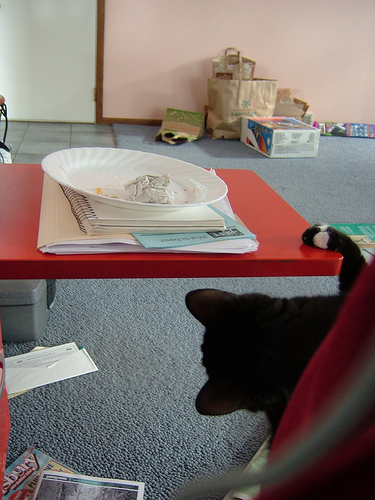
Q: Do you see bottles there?
A: No, there are no bottles.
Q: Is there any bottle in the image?
A: No, there are no bottles.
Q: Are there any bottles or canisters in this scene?
A: No, there are no bottles or canisters.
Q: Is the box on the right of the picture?
A: Yes, the box is on the right of the image.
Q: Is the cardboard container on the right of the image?
A: Yes, the box is on the right of the image.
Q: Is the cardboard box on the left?
A: No, the box is on the right of the image.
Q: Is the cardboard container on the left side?
A: No, the box is on the right of the image.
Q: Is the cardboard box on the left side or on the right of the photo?
A: The box is on the right of the image.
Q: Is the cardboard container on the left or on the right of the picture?
A: The box is on the right of the image.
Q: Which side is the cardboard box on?
A: The box is on the right of the image.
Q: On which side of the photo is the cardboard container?
A: The box is on the right of the image.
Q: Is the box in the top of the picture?
A: Yes, the box is in the top of the image.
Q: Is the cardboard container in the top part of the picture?
A: Yes, the box is in the top of the image.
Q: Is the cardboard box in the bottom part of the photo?
A: No, the box is in the top of the image.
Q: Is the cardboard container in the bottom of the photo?
A: No, the box is in the top of the image.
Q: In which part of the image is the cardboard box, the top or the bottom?
A: The box is in the top of the image.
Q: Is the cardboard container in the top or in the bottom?
A: The box is in the top of the image.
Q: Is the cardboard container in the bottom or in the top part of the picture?
A: The box is in the top of the image.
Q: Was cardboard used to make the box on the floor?
A: Yes, the box is made of cardboard.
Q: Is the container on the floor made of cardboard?
A: Yes, the box is made of cardboard.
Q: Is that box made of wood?
A: No, the box is made of cardboard.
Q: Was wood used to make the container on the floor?
A: No, the box is made of cardboard.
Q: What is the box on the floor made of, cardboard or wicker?
A: The box is made of cardboard.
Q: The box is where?
A: The box is on the floor.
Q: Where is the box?
A: The box is on the floor.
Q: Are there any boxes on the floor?
A: Yes, there is a box on the floor.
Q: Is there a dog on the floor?
A: No, there is a box on the floor.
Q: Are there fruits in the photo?
A: No, there are no fruits.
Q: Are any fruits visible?
A: No, there are no fruits.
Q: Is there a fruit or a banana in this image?
A: No, there are no fruits or bananas.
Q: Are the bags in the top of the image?
A: Yes, the bags are in the top of the image.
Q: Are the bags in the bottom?
A: No, the bags are in the top of the image.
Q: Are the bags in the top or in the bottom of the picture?
A: The bags are in the top of the image.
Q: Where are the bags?
A: The bags are on the floor.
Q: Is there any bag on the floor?
A: Yes, there are bags on the floor.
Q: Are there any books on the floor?
A: No, there are bags on the floor.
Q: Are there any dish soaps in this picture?
A: No, there are no dish soaps.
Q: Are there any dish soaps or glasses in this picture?
A: No, there are no dish soaps or glasses.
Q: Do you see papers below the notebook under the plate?
A: Yes, there are papers below the notebook.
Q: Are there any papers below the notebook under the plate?
A: Yes, there are papers below the notebook.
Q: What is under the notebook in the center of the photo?
A: The papers are under the notebook.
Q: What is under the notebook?
A: The papers are under the notebook.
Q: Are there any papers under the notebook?
A: Yes, there are papers under the notebook.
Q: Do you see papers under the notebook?
A: Yes, there are papers under the notebook.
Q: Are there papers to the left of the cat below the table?
A: Yes, there are papers to the left of the cat.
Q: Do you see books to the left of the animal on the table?
A: No, there are papers to the left of the cat.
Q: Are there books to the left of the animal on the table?
A: No, there are papers to the left of the cat.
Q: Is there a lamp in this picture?
A: No, there are no lamps.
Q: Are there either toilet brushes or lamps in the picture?
A: No, there are no lamps or toilet brushes.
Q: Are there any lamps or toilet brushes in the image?
A: No, there are no lamps or toilet brushes.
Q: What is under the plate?
A: The notebook is under the plate.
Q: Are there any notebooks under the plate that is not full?
A: Yes, there is a notebook under the plate.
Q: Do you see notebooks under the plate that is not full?
A: Yes, there is a notebook under the plate.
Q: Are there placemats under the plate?
A: No, there is a notebook under the plate.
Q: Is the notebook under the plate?
A: Yes, the notebook is under the plate.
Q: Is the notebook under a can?
A: No, the notebook is under the plate.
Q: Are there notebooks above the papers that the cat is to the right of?
A: Yes, there is a notebook above the papers.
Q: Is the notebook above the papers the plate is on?
A: Yes, the notebook is above the papers.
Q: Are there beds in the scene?
A: No, there are no beds.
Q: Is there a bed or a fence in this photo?
A: No, there are no beds or fences.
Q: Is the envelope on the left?
A: Yes, the envelope is on the left of the image.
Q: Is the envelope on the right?
A: No, the envelope is on the left of the image.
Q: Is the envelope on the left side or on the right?
A: The envelope is on the left of the image.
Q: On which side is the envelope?
A: The envelope is on the left of the image.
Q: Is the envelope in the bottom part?
A: Yes, the envelope is in the bottom of the image.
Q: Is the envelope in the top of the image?
A: No, the envelope is in the bottom of the image.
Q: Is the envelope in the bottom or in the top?
A: The envelope is in the bottom of the image.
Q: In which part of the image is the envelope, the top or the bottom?
A: The envelope is in the bottom of the image.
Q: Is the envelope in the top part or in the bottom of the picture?
A: The envelope is in the bottom of the image.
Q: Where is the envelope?
A: The envelope is on the floor.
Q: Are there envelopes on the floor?
A: Yes, there is an envelope on the floor.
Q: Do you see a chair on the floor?
A: No, there is an envelope on the floor.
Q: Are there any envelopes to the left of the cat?
A: Yes, there is an envelope to the left of the cat.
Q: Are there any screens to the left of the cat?
A: No, there is an envelope to the left of the cat.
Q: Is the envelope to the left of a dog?
A: No, the envelope is to the left of the cat.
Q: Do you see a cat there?
A: Yes, there is a cat.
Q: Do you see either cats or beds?
A: Yes, there is a cat.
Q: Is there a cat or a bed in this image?
A: Yes, there is a cat.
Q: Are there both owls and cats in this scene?
A: No, there is a cat but no owls.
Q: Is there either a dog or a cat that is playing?
A: Yes, the cat is playing.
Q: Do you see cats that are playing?
A: Yes, there is a cat that is playing.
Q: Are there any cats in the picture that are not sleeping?
A: Yes, there is a cat that is playing.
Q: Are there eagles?
A: No, there are no eagles.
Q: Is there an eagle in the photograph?
A: No, there are no eagles.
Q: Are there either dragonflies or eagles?
A: No, there are no eagles or dragonflies.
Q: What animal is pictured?
A: The animal is a cat.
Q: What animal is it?
A: The animal is a cat.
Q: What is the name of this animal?
A: This is a cat.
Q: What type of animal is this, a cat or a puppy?
A: This is a cat.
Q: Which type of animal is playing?
A: The animal is a cat.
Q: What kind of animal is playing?
A: The animal is a cat.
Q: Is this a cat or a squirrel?
A: This is a cat.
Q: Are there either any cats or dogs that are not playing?
A: No, there is a cat but it is playing.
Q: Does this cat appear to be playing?
A: Yes, the cat is playing.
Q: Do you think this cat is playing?
A: Yes, the cat is playing.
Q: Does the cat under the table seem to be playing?
A: Yes, the cat is playing.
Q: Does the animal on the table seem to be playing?
A: Yes, the cat is playing.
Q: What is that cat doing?
A: The cat is playing.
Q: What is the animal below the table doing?
A: The cat is playing.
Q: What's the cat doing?
A: The cat is playing.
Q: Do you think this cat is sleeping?
A: No, the cat is playing.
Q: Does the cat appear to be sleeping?
A: No, the cat is playing.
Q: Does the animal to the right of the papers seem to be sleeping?
A: No, the cat is playing.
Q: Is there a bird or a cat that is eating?
A: No, there is a cat but it is playing.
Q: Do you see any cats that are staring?
A: No, there is a cat but it is playing.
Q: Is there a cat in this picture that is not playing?
A: No, there is a cat but it is playing.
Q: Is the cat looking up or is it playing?
A: The cat is playing.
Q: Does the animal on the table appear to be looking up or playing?
A: The cat is playing.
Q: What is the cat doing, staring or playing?
A: The cat is playing.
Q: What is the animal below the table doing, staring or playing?
A: The cat is playing.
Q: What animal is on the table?
A: The animal is a cat.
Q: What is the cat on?
A: The cat is on the table.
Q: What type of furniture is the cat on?
A: The cat is on the table.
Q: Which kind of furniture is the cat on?
A: The cat is on the table.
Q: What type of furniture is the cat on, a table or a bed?
A: The cat is on a table.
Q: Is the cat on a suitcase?
A: No, the cat is on a table.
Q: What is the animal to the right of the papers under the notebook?
A: The animal is a cat.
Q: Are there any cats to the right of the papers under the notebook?
A: Yes, there is a cat to the right of the papers.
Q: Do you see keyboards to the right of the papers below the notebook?
A: No, there is a cat to the right of the papers.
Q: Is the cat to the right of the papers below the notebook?
A: Yes, the cat is to the right of the papers.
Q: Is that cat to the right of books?
A: No, the cat is to the right of the papers.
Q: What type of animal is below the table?
A: The animal is a cat.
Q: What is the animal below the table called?
A: The animal is a cat.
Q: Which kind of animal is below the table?
A: The animal is a cat.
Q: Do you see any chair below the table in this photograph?
A: No, there is a cat below the table.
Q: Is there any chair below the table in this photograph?
A: No, there is a cat below the table.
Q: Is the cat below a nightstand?
A: No, the cat is below the table.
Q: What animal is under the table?
A: The animal is a cat.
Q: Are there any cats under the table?
A: Yes, there is a cat under the table.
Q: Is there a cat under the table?
A: Yes, there is a cat under the table.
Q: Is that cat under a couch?
A: No, the cat is under the table.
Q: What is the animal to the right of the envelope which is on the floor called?
A: The animal is a cat.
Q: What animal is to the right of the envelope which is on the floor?
A: The animal is a cat.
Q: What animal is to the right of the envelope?
A: The animal is a cat.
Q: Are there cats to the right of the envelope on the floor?
A: Yes, there is a cat to the right of the envelope.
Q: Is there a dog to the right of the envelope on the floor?
A: No, there is a cat to the right of the envelope.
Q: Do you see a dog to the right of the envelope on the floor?
A: No, there is a cat to the right of the envelope.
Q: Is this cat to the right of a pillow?
A: No, the cat is to the right of the envelope.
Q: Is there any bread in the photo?
A: No, there is no breads.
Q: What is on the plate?
A: The napkin is on the plate.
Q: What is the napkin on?
A: The napkin is on the plate.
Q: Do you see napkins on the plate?
A: Yes, there is a napkin on the plate.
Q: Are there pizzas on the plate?
A: No, there is a napkin on the plate.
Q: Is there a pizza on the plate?
A: No, there is a napkin on the plate.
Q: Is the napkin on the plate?
A: Yes, the napkin is on the plate.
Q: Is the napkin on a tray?
A: No, the napkin is on the plate.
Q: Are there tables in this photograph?
A: Yes, there is a table.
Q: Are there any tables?
A: Yes, there is a table.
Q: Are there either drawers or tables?
A: Yes, there is a table.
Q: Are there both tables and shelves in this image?
A: No, there is a table but no shelves.